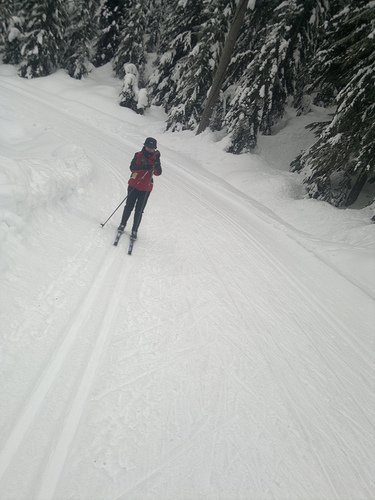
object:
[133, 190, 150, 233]
leg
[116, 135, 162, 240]
lady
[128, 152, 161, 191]
coat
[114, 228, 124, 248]
ski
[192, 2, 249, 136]
tree trunk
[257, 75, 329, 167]
wall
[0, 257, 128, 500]
marks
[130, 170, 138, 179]
pocket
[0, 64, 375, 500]
snow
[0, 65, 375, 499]
ground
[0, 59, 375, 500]
ski trail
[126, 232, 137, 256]
ski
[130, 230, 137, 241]
foot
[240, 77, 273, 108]
ground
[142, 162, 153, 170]
glove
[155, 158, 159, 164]
hand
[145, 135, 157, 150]
hat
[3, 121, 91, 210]
side bank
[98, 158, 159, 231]
ski pole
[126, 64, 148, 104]
snow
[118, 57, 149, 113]
tree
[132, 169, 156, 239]
ski pole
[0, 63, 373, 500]
slope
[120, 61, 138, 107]
branch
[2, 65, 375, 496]
trail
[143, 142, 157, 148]
visor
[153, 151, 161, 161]
hand